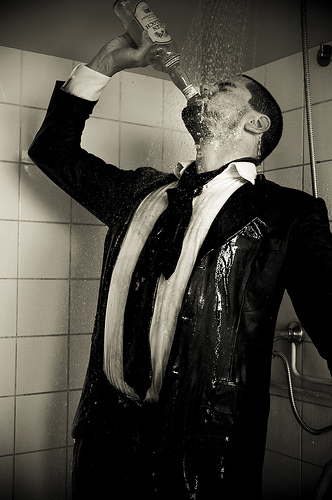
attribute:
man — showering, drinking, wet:
[28, 32, 332, 499]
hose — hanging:
[291, 8, 322, 197]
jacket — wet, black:
[28, 80, 331, 487]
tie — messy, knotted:
[121, 156, 262, 399]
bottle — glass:
[111, 1, 204, 103]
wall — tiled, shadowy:
[0, 0, 331, 497]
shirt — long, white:
[54, 61, 260, 407]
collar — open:
[173, 159, 261, 187]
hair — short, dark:
[236, 68, 285, 164]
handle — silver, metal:
[277, 319, 308, 353]